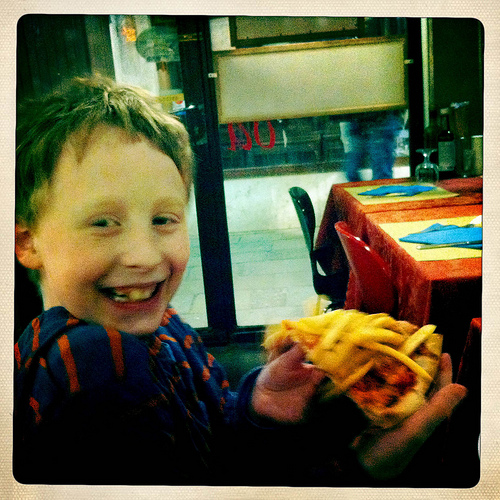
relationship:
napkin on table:
[404, 211, 484, 253] [317, 179, 482, 389]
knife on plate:
[413, 233, 482, 258] [396, 213, 484, 275]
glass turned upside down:
[409, 142, 444, 187] [410, 135, 451, 196]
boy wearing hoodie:
[15, 74, 324, 482] [14, 305, 382, 486]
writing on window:
[217, 100, 315, 177] [201, 37, 421, 297]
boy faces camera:
[15, 74, 324, 482] [44, 132, 372, 477]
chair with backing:
[288, 187, 351, 303] [263, 179, 326, 307]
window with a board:
[172, 18, 440, 326] [202, 15, 430, 125]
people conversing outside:
[331, 109, 403, 183] [228, 43, 429, 206]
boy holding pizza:
[15, 74, 470, 488] [257, 292, 447, 432]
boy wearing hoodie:
[15, 74, 470, 488] [23, 305, 226, 406]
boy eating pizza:
[15, 74, 470, 488] [262, 295, 446, 442]